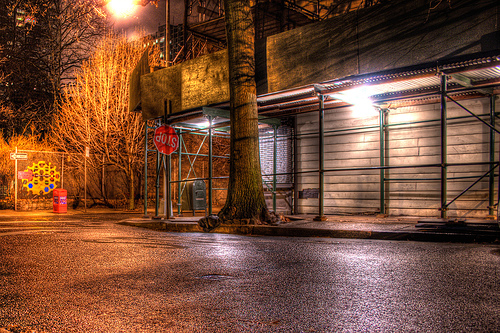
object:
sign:
[10, 153, 29, 161]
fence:
[0, 148, 218, 210]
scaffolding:
[141, 13, 498, 83]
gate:
[18, 150, 91, 242]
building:
[127, 11, 500, 226]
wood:
[128, 44, 154, 120]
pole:
[163, 154, 175, 219]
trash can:
[53, 187, 68, 214]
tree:
[198, 0, 290, 232]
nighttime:
[91, 0, 147, 20]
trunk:
[199, 184, 290, 231]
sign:
[7, 148, 30, 162]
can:
[179, 177, 207, 217]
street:
[0, 230, 500, 331]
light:
[329, 81, 391, 121]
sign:
[152, 124, 180, 155]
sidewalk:
[280, 215, 492, 237]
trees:
[3, 0, 105, 202]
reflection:
[193, 227, 460, 332]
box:
[52, 188, 68, 213]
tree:
[52, 26, 161, 209]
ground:
[0, 212, 498, 329]